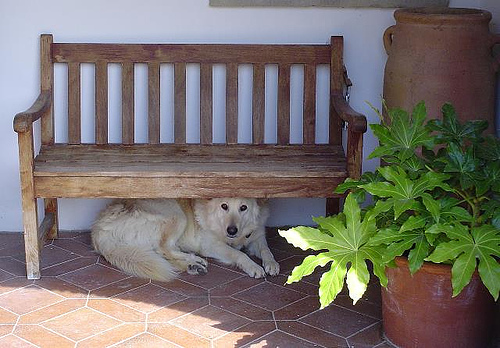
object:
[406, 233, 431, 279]
leaf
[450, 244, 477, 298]
leaf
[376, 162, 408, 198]
leaf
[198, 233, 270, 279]
leg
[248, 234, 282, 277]
leg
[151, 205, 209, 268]
leg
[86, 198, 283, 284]
dog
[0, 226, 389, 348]
floor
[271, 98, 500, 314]
plant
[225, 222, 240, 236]
black nose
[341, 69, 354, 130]
chain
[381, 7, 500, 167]
pot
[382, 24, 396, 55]
handle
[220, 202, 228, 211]
eyes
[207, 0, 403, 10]
window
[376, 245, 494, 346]
pot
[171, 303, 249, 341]
tiles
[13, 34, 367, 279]
bench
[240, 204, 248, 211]
eyes